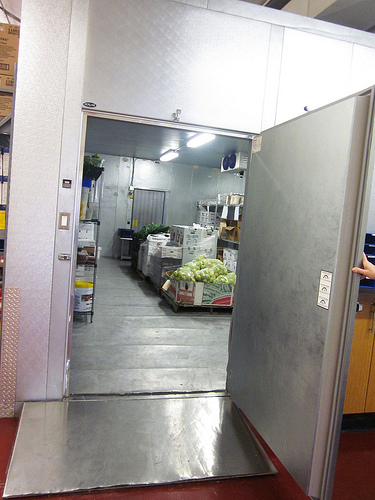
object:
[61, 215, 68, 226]
switch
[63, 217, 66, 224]
white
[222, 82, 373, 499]
door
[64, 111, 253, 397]
cooler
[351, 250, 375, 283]
hand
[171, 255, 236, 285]
apples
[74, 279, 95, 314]
bucket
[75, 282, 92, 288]
yellow lid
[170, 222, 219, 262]
boxes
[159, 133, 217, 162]
light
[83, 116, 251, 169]
ceiling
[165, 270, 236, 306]
box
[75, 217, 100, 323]
shelving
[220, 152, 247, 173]
fan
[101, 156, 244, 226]
wall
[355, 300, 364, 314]
handle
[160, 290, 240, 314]
palette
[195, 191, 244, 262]
shelving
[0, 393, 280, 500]
board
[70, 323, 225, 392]
floor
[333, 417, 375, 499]
floor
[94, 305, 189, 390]
lines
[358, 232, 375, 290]
cabinet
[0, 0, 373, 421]
cooling unit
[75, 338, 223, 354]
seam